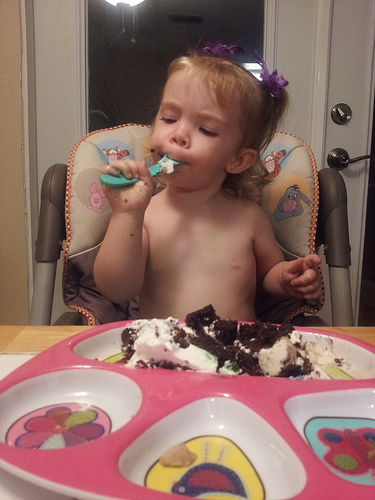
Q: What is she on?
A: Seat.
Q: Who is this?
A: Baby.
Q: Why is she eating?
A: Hungry.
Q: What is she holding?
A: Spoon.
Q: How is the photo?
A: Clear.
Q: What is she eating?
A: Food.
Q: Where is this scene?
A: At a table.